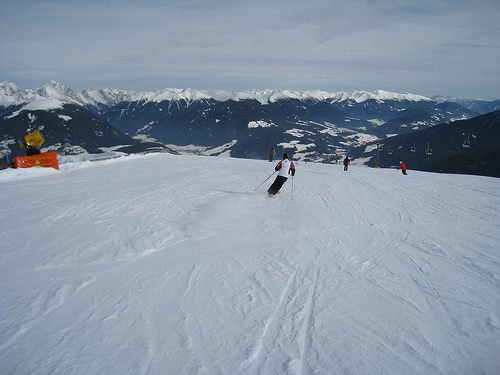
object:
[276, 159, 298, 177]
jacket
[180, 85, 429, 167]
mountain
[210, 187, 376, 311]
snow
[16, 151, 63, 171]
sign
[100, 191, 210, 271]
mark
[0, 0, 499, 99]
sky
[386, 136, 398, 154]
lift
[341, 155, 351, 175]
people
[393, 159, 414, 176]
skiers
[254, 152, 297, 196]
skier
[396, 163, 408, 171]
coat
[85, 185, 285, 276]
ground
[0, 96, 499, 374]
hill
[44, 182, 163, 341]
tracks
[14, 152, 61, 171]
netting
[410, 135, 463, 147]
metal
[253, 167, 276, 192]
pole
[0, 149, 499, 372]
hill